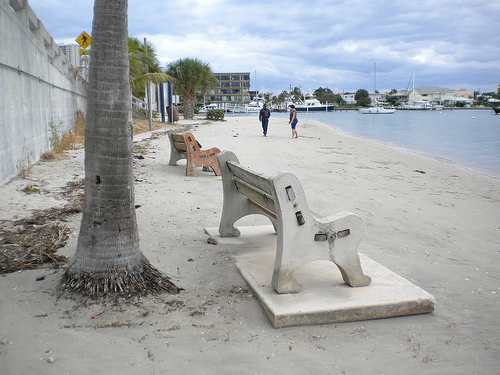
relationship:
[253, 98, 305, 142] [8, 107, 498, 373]
couple on beach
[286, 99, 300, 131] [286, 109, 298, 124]
woman wearing suit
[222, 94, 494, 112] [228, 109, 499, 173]
boats in sea water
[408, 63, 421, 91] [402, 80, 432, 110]
pole on boat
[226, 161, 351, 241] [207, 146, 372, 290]
wood/concrete bench on bench